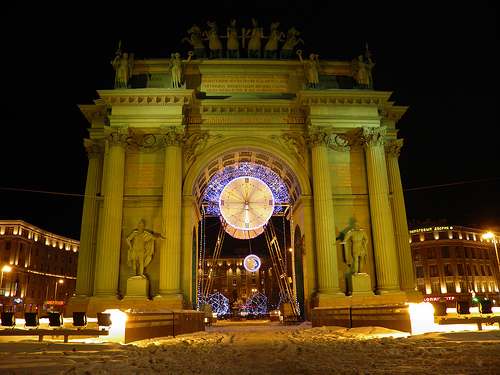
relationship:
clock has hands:
[213, 172, 278, 239] [226, 179, 254, 206]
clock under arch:
[213, 172, 278, 239] [182, 137, 311, 195]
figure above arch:
[182, 129, 222, 163] [182, 137, 311, 195]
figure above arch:
[272, 130, 308, 165] [182, 137, 311, 195]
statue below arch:
[124, 218, 163, 302] [182, 137, 311, 195]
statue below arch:
[340, 217, 373, 300] [182, 137, 311, 195]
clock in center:
[213, 172, 278, 239] [187, 167, 311, 231]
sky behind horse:
[2, 1, 499, 217] [178, 22, 206, 57]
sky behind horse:
[2, 1, 499, 217] [201, 16, 222, 57]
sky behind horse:
[2, 1, 499, 217] [222, 16, 242, 60]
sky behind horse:
[2, 1, 499, 217] [247, 16, 267, 57]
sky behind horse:
[2, 1, 499, 217] [264, 18, 283, 59]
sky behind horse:
[2, 1, 499, 217] [281, 25, 304, 59]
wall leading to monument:
[102, 307, 207, 341] [67, 18, 436, 334]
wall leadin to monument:
[311, 299, 441, 335] [67, 18, 436, 334]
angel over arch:
[182, 129, 222, 163] [182, 137, 311, 195]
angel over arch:
[272, 130, 308, 165] [182, 137, 311, 195]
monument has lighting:
[67, 18, 436, 334] [201, 162, 294, 214]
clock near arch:
[213, 172, 278, 239] [182, 137, 311, 195]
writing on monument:
[187, 72, 300, 93] [67, 18, 436, 334]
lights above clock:
[201, 162, 294, 214] [213, 172, 278, 239]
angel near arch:
[182, 129, 222, 163] [182, 137, 311, 195]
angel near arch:
[272, 130, 308, 165] [182, 137, 311, 195]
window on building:
[429, 284, 444, 299] [406, 219, 499, 317]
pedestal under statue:
[121, 272, 154, 300] [124, 218, 163, 302]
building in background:
[406, 219, 499, 317] [4, 213, 500, 340]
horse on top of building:
[178, 22, 206, 57] [67, 18, 436, 334]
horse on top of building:
[201, 16, 222, 57] [67, 18, 436, 334]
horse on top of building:
[222, 16, 242, 60] [67, 18, 436, 334]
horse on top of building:
[247, 16, 267, 57] [67, 18, 436, 334]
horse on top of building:
[264, 18, 283, 59] [67, 18, 436, 334]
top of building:
[111, 57, 377, 96] [67, 18, 436, 334]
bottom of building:
[70, 215, 416, 329] [67, 18, 436, 334]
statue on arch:
[124, 218, 163, 302] [159, 88, 331, 330]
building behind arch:
[406, 219, 499, 317] [153, 189, 352, 310]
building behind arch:
[4, 219, 79, 321] [153, 189, 352, 310]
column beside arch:
[309, 138, 340, 292] [176, 185, 322, 325]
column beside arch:
[92, 135, 126, 300] [190, 185, 300, 321]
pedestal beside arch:
[158, 125, 187, 309] [190, 185, 300, 321]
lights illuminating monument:
[200, 219, 226, 320] [96, 46, 433, 326]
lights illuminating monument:
[265, 214, 298, 320] [96, 46, 433, 326]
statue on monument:
[106, 40, 135, 92] [96, 60, 409, 330]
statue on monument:
[167, 48, 194, 93] [96, 60, 409, 330]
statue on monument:
[295, 50, 325, 91] [96, 60, 409, 330]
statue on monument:
[350, 41, 378, 91] [96, 60, 409, 330]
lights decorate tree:
[208, 291, 227, 312] [197, 292, 228, 321]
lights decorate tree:
[248, 289, 270, 311] [245, 292, 270, 317]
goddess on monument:
[109, 54, 130, 92] [85, 68, 416, 321]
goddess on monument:
[349, 46, 379, 85] [85, 68, 416, 321]